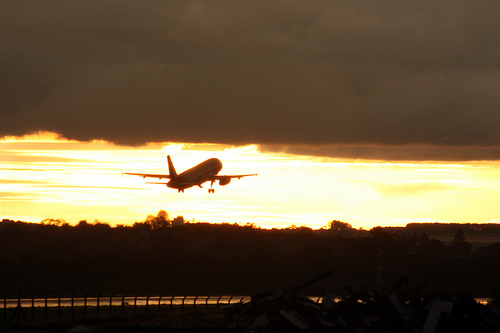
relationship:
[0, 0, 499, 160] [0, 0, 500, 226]
clouds in sky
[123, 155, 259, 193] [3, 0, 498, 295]
plane in air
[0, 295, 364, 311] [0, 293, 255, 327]
rubway behind fence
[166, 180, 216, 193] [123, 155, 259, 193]
gear on aircraft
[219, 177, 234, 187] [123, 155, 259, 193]
engine on aircraft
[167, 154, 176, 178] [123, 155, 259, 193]
tail end of aircraft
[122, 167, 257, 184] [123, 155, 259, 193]
wingspan of aircraft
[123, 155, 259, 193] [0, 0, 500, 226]
plane in sky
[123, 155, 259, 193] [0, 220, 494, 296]
plane over trees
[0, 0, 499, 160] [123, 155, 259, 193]
clouds over plane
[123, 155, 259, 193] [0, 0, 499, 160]
plane under clouds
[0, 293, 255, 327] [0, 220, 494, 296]
fence along trees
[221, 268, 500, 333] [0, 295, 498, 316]
rubble near landing strip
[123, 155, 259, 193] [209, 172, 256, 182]
plane has wing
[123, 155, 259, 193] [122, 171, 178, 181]
plane has wing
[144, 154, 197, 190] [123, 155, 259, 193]
tail of plane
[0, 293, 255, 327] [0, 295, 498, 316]
fence along landing strip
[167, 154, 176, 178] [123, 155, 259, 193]
stabilizer on plane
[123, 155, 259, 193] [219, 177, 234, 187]
plane has engine